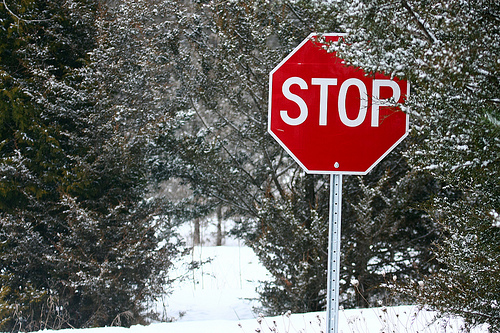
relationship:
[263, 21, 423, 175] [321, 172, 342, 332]
stop sign on post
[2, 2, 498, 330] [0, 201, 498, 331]
snow on ground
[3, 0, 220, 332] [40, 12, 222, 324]
tree cover with snow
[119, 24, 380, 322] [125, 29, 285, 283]
tree covered with snow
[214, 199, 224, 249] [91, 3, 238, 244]
trunk of tree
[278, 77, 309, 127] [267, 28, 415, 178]
letter s on sign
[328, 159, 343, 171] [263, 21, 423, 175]
bolt fixes a stop sign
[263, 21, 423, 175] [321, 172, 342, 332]
stop sign fixed to a post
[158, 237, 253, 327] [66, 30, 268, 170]
pathway between trees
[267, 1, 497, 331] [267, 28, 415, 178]
tree behind sign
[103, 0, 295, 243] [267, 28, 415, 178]
tree behind sign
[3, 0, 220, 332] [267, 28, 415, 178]
tree behind sign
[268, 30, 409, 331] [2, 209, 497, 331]
sign in snow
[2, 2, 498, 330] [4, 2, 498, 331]
snow on branches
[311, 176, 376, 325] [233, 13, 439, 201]
metal pole with sign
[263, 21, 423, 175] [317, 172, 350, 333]
stop sign on metal pole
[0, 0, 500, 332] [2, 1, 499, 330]
trees has leaves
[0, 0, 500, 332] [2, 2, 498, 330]
trees has snow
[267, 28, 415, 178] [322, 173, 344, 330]
sign on pole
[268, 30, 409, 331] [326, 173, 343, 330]
sign on pole